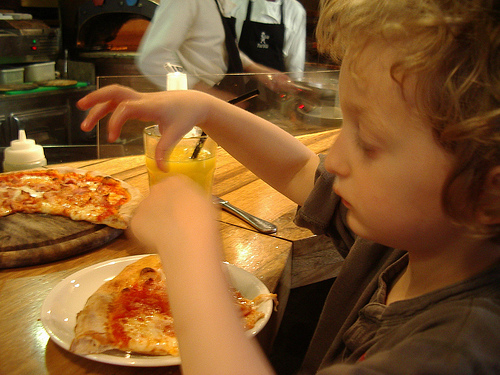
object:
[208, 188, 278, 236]
untensil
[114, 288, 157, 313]
sauce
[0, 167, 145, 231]
pizza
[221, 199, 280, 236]
handle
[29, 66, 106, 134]
glass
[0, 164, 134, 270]
board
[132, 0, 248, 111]
chef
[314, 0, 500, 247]
hair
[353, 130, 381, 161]
eye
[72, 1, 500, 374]
boy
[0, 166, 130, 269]
dish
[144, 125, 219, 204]
glass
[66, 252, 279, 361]
pizza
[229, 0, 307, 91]
people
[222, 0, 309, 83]
shirt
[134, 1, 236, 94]
shirt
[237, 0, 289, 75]
apron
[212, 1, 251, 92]
apron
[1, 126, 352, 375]
table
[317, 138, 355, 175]
nose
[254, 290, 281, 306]
cheese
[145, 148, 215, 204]
liquid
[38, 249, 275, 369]
plate